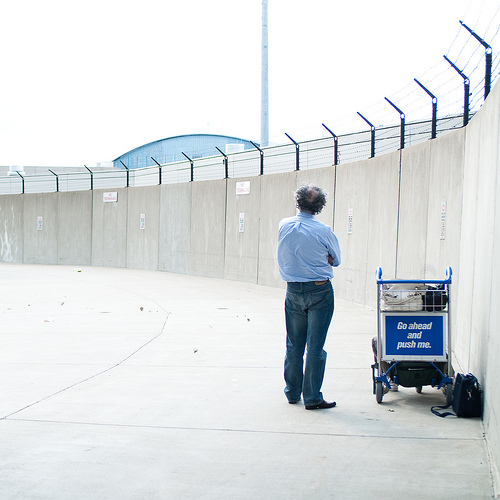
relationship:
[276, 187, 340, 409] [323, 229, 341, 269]
man crossing arms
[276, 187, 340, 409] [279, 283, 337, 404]
man wearing jeans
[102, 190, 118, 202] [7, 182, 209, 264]
sign posted wall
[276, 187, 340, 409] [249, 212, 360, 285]
man wearing shirt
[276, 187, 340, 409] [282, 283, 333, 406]
man wearing jeans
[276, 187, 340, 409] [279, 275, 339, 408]
man wearing jeans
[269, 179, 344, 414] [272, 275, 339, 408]
man wearing jeans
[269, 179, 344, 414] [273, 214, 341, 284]
man wearing shirt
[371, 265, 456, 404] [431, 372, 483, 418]
cart for bag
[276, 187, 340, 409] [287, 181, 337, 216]
man with hair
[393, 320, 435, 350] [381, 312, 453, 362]
words on sign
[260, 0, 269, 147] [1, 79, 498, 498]
pole beyond wall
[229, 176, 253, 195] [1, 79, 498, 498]
sign posted on wall